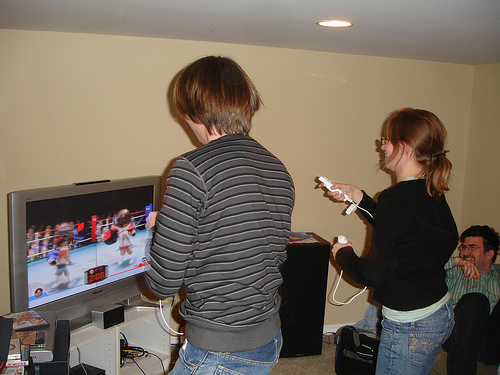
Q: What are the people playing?
A: Wii Boxing.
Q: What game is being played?
A: WII.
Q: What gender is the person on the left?
A: Male.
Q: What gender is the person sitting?
A: Male.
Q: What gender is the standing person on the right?
A: Female.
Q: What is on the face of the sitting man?
A: Glasses.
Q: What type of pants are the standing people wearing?
A: Blue jeans.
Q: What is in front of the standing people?
A: TV.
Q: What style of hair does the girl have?
A: Long.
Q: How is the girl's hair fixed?
A: Ponytail.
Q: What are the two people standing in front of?
A: Television.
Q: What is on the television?
A: Video game.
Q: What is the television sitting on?
A: White table.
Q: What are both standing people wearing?
A: Blue jeans.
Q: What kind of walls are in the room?
A: Tan walls.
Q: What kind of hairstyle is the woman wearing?
A: Ponytail.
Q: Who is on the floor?
A: Man in eye glasses and green striped shirt.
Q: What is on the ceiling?
A: One round recessed lighting.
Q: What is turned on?
A: TV screen.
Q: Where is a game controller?
A: In woman's hand.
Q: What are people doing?
A: Playing video game.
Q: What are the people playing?
A: Video game.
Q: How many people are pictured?
A: Three.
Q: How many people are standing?
A: Two.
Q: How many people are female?
A: One.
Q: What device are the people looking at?
A: Television.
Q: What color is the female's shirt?
A: Black.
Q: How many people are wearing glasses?
A: Two.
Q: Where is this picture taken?
A: In the living room.